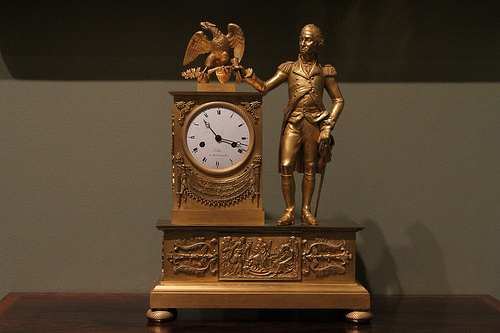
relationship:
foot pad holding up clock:
[144, 308, 180, 323] [146, 20, 374, 326]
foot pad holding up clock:
[344, 310, 374, 323] [146, 20, 374, 326]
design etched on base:
[165, 236, 218, 277] [149, 219, 371, 310]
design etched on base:
[217, 231, 301, 281] [149, 219, 371, 310]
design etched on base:
[301, 238, 354, 280] [149, 219, 371, 310]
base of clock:
[149, 219, 371, 310] [146, 20, 374, 326]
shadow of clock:
[355, 217, 447, 316] [146, 20, 374, 326]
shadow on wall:
[355, 217, 447, 316] [0, 82, 499, 294]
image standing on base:
[240, 22, 345, 226] [149, 219, 371, 310]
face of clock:
[186, 108, 251, 170] [146, 20, 374, 326]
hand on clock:
[203, 119, 223, 142] [146, 20, 374, 326]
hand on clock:
[214, 135, 249, 147] [146, 20, 374, 326]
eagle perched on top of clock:
[181, 21, 244, 80] [146, 20, 374, 326]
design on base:
[217, 231, 301, 281] [149, 219, 371, 310]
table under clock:
[1, 291, 499, 332] [146, 20, 374, 326]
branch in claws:
[181, 65, 245, 80] [195, 71, 212, 82]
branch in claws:
[181, 65, 245, 80] [221, 65, 234, 73]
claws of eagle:
[195, 71, 212, 82] [181, 21, 244, 80]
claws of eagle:
[221, 65, 234, 73] [181, 21, 244, 80]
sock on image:
[281, 175, 296, 211] [240, 22, 345, 226]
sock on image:
[301, 174, 316, 206] [240, 22, 345, 226]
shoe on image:
[276, 213, 295, 226] [240, 22, 345, 226]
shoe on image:
[301, 213, 318, 226] [240, 22, 345, 226]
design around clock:
[165, 236, 218, 277] [146, 20, 374, 326]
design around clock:
[217, 231, 301, 281] [146, 20, 374, 326]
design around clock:
[301, 238, 354, 280] [146, 20, 374, 326]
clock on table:
[146, 20, 374, 326] [1, 291, 499, 332]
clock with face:
[146, 20, 374, 326] [186, 108, 251, 170]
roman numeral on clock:
[215, 109, 223, 117] [146, 20, 374, 326]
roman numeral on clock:
[238, 123, 244, 129] [146, 20, 374, 326]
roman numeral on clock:
[235, 148, 245, 156] [146, 20, 374, 326]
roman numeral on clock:
[201, 155, 208, 165] [146, 20, 374, 326]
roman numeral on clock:
[188, 134, 196, 142] [146, 20, 374, 326]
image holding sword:
[240, 22, 345, 226] [312, 139, 331, 218]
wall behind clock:
[0, 82, 499, 294] [146, 20, 374, 326]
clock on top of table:
[146, 20, 374, 326] [1, 291, 499, 332]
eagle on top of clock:
[181, 21, 244, 80] [146, 20, 374, 326]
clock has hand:
[146, 20, 374, 326] [203, 119, 223, 142]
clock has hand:
[146, 20, 374, 326] [214, 135, 249, 147]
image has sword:
[240, 22, 345, 226] [312, 139, 331, 218]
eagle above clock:
[181, 21, 244, 80] [146, 20, 374, 326]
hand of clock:
[203, 119, 223, 142] [146, 20, 374, 326]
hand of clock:
[214, 135, 249, 147] [146, 20, 374, 326]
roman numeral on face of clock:
[215, 109, 223, 117] [146, 20, 374, 326]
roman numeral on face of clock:
[238, 123, 244, 129] [146, 20, 374, 326]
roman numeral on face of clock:
[235, 148, 245, 156] [146, 20, 374, 326]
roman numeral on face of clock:
[201, 155, 208, 165] [146, 20, 374, 326]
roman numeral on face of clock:
[188, 134, 196, 142] [146, 20, 374, 326]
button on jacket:
[309, 75, 315, 81] [244, 53, 345, 174]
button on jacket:
[307, 80, 312, 86] [244, 53, 345, 174]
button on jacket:
[308, 84, 313, 90] [244, 53, 345, 174]